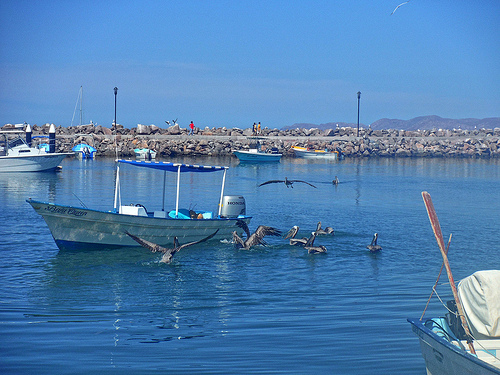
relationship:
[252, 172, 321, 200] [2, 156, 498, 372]
bird flying over water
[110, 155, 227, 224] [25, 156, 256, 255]
canopy on top of boat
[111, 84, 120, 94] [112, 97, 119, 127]
street lamp on pole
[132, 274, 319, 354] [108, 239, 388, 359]
ripples are in water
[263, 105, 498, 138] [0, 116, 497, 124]
mountain visible in horizon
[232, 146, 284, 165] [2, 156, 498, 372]
boat in water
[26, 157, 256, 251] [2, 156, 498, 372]
boat in water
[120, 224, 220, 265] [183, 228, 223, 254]
bird spreading its wing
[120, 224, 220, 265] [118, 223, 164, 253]
bird spreading its wing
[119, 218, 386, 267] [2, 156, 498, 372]
birds floating in water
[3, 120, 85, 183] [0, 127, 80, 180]
boat at dock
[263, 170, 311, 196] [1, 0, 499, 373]
pelican flying in air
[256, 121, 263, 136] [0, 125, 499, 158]
person on beach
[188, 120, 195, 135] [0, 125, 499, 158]
person on beach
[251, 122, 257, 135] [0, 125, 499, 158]
person on beach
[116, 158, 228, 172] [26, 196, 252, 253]
roof on boat